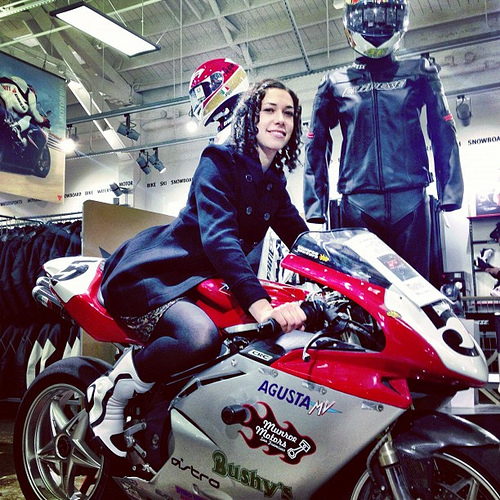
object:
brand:
[258, 377, 338, 412]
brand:
[221, 398, 317, 466]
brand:
[211, 449, 291, 498]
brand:
[170, 457, 220, 488]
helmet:
[186, 56, 250, 126]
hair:
[232, 78, 306, 173]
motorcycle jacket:
[303, 56, 466, 232]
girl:
[83, 78, 327, 463]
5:
[420, 298, 485, 359]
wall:
[467, 139, 498, 184]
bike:
[11, 224, 499, 499]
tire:
[343, 440, 498, 500]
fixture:
[46, 0, 158, 56]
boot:
[85, 343, 157, 463]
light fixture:
[129, 145, 167, 179]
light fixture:
[454, 94, 471, 129]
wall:
[8, 106, 70, 210]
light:
[62, 136, 76, 157]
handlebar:
[255, 299, 351, 364]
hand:
[261, 300, 306, 332]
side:
[12, 225, 499, 497]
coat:
[100, 139, 311, 315]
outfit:
[303, 0, 463, 290]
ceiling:
[0, 0, 499, 128]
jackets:
[4, 324, 79, 441]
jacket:
[103, 133, 300, 320]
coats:
[3, 223, 80, 400]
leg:
[84, 301, 226, 460]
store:
[0, 1, 499, 498]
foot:
[76, 332, 153, 465]